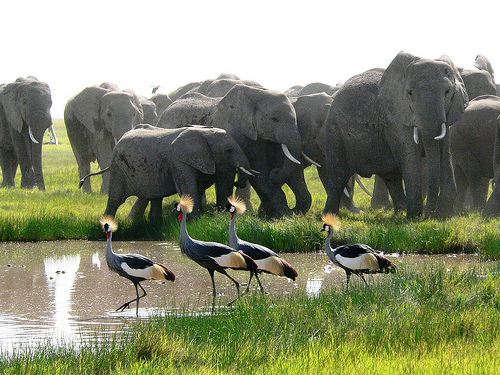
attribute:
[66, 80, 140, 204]
elephant — grey 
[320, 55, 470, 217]
elephant — grey 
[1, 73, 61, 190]
elephant — grey 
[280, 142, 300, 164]
tusk — long, white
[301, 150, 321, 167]
tusk — long, white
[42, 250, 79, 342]
reflection — light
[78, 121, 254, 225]
elephant — young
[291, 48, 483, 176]
elephant — grey 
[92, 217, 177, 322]
bird — white, black, lead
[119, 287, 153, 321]
legs — long, spindly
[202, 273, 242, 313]
legs — long, spindly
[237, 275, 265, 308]
legs — long, spindly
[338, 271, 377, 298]
legs — long, spindly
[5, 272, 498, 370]
grass — tan, yellow, green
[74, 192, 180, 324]
bird — black, white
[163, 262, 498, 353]
grass — green, tall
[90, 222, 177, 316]
bird — large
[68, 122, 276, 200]
elephant — grey 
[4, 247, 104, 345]
pond water — murky, brown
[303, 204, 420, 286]
bird — black, white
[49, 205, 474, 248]
grass — green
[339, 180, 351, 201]
tusks — elephant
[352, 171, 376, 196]
tusks — elephant